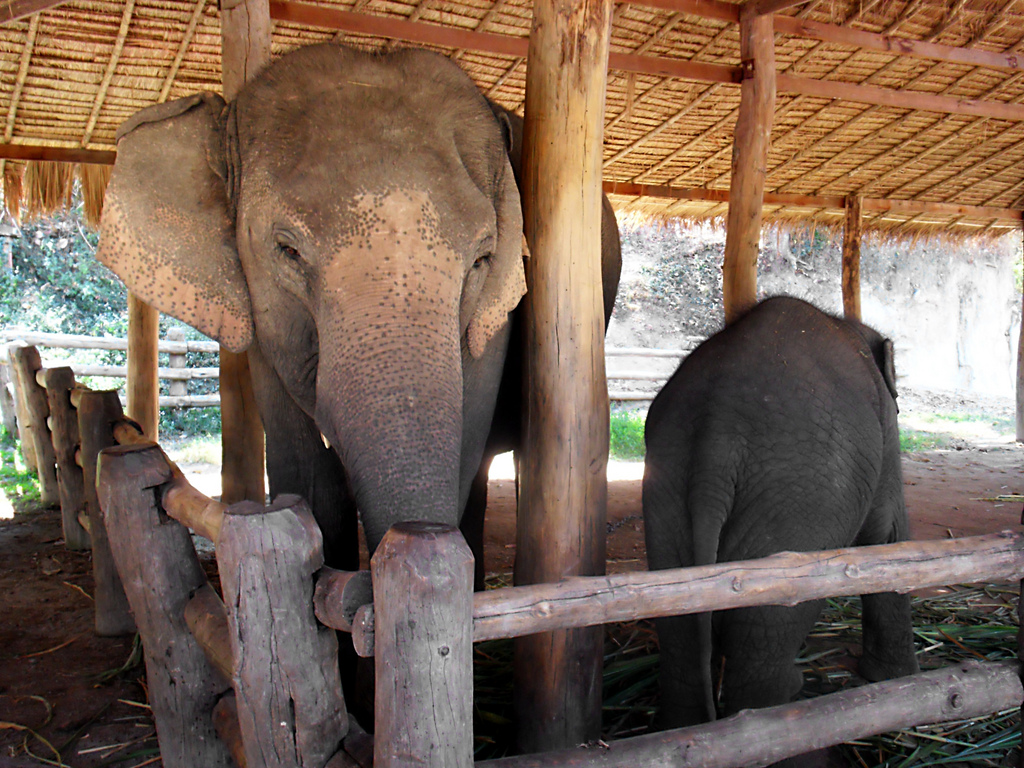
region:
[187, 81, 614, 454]
the head of a elephant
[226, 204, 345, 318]
the eye of a elephant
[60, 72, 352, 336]
the ear of a elephant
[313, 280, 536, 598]
the trunk of a elephant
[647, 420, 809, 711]
the tail of a elephant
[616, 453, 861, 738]
the back legs of a elephant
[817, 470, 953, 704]
the front leg of a elephant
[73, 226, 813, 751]
a fence around a elephant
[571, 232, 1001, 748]
a small grey elaphant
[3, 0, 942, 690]
two elephants under a ramada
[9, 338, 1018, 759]
low split-rail fence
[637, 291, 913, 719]
elephant has tail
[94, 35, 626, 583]
elephant has right ear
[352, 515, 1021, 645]
top rail of split-rail fence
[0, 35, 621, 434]
vegetation behind elephant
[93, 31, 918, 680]
one elephant is smaller than other elephant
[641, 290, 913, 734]
small baby elephant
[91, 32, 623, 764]
large elephant with a light colored speckled face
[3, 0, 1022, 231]
thatch roof pen covering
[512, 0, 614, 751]
wooden roof support beam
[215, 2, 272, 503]
wooden roof support beam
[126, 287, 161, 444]
wooden roof support beam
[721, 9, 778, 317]
wooden roof support beam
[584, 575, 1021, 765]
green reeds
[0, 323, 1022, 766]
fencing partially enclosing a pen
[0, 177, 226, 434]
green climbing vines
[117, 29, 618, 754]
A large elephant in a pen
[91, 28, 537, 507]
Elephants head gray and tanish color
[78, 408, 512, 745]
A wooden post fence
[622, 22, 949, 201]
A wooden slat roof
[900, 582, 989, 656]
Straw in the elephants pen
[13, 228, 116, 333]
Trees on the other side of pen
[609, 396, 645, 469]
Green grass on other side of fence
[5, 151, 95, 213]
Rafia trim hanging off the roof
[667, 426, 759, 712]
Small elephants tail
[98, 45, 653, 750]
a large elephant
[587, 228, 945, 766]
a baby elephant in fence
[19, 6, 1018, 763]
two elephants in a fence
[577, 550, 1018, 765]
grass on the dirt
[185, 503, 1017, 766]
a grey wooden fence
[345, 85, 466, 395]
spots on the elephants skin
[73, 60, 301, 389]
the ear on a elephant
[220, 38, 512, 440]
the face of a large elephant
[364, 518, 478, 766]
the corner fence post of the cage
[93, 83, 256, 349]
the ear of an elephant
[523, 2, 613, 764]
a floor to ceiling support pole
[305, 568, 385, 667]
two fence rails close to each other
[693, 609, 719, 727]
the tail of an elephant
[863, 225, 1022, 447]
the glare of sunshine